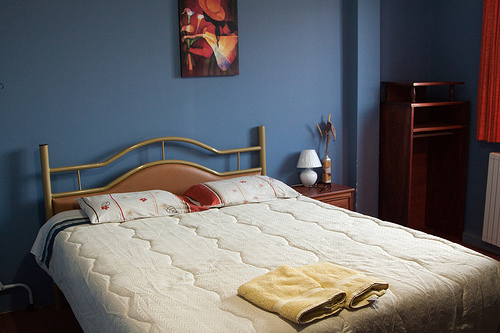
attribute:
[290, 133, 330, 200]
lamp — white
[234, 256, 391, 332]
towels — yellow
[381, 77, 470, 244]
tall furniture — wooden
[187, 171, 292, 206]
pillow case — white, red, black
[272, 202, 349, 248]
bedspread — white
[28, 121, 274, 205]
headboard — brown, metal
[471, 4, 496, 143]
red curtain — long, bright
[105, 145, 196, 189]
headboard — tan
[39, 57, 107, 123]
wall — blue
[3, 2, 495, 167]
walls — blue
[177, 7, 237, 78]
painting — orange, black, yellow, green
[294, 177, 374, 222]
table — small, wooden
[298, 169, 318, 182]
lamp — small, white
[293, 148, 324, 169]
lamp shade — white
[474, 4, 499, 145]
curtain — red